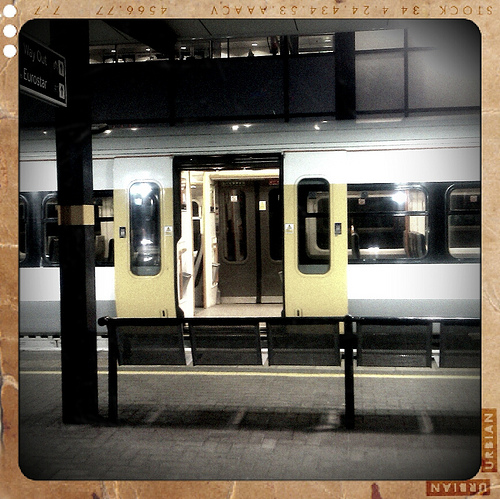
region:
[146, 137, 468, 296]
this is a train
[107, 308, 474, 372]
this is a bench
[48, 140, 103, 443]
this is a pillar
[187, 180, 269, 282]
this is the door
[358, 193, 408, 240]
this is the window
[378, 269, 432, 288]
the train is white in color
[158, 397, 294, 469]
this is a pavement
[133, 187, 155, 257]
this is a window pane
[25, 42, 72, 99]
this is a signpost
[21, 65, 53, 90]
this is a writing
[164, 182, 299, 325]
this is a doorway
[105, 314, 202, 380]
this is the first sign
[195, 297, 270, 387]
this is the second sign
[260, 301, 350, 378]
this is the third sign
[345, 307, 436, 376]
this is the 4th sign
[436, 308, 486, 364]
this is a sign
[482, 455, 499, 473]
the brown letter u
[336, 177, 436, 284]
a underground train window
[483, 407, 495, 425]
brown letter capital N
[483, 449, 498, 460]
the brown capital r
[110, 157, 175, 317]
the door is white and yellow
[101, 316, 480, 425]
there is a black bench on the platform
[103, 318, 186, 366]
the bench is broken up into sections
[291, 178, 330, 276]
the window is in the door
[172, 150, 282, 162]
the mechanism that slides the doors open and closed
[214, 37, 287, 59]
window looking out over the train platform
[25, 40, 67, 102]
sign on the post next to the bench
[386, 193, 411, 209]
platform light reflecting off the glass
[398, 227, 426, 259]
seats inside the train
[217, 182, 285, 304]
the inside of the doors are silver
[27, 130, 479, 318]
a train stopped on at a station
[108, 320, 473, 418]
a bench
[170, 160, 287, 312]
an open train door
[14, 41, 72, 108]
a sign indicating destination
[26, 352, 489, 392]
painted line indicating a safe distance from the train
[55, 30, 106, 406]
a metal support pole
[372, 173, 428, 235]
light glare reflecting off of train window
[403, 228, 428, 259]
seats in the train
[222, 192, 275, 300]
a closed train door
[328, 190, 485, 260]
windows on the train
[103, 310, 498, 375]
Bench for subway stop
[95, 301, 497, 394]
Five seats on bench for subway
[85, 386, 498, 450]
Shadow underneath subway bench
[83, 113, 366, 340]
Doors opening for subway train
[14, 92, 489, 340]
Yellow and white subway train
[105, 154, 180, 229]
Light reflecting off subway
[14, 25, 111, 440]
Black pole to the left of bench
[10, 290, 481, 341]
Thick grey line on bottom of subway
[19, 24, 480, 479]
Empty subway train station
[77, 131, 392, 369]
Two yellow subway doors